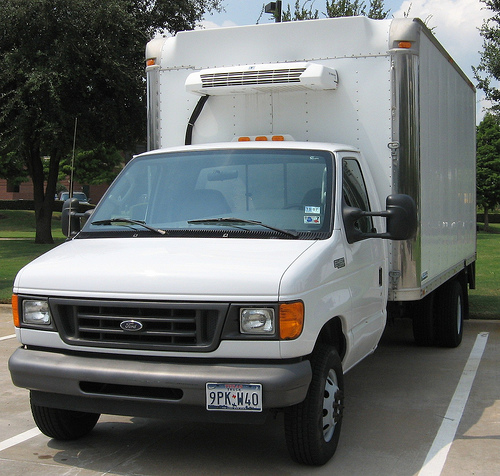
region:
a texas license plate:
[202, 370, 272, 431]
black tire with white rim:
[302, 368, 348, 462]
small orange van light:
[276, 288, 308, 350]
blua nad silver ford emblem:
[105, 308, 160, 356]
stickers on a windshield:
[294, 200, 322, 243]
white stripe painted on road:
[400, 329, 498, 474]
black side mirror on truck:
[331, 189, 415, 271]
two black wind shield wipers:
[80, 213, 270, 253]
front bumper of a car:
[10, 351, 295, 431]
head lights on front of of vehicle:
[0, 290, 292, 364]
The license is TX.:
[184, 376, 273, 430]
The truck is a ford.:
[109, 310, 154, 345]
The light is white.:
[241, 294, 303, 348]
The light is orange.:
[277, 294, 309, 341]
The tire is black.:
[293, 354, 383, 468]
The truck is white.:
[32, 19, 487, 471]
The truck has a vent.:
[178, 49, 351, 122]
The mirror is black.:
[358, 189, 438, 254]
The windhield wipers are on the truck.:
[79, 203, 314, 242]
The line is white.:
[397, 319, 457, 474]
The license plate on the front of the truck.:
[204, 376, 264, 415]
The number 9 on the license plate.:
[207, 389, 219, 404]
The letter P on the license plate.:
[214, 392, 225, 405]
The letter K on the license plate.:
[222, 387, 233, 408]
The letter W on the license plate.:
[236, 388, 243, 406]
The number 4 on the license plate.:
[244, 392, 254, 404]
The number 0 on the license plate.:
[251, 390, 258, 405]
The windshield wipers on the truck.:
[96, 206, 286, 243]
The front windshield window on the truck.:
[104, 150, 329, 237]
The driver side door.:
[336, 156, 393, 356]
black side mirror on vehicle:
[360, 166, 430, 257]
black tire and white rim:
[282, 350, 359, 471]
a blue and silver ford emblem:
[102, 315, 155, 345]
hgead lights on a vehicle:
[220, 285, 317, 367]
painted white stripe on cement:
[387, 325, 492, 473]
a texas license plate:
[184, 364, 279, 469]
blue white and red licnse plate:
[157, 379, 271, 454]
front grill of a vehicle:
[15, 285, 219, 385]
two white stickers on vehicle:
[248, 199, 333, 260]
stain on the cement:
[2, 445, 79, 471]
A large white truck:
[46, 14, 493, 451]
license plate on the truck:
[200, 377, 299, 426]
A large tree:
[3, 0, 207, 242]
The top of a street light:
[249, 0, 298, 20]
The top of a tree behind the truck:
[283, 0, 427, 26]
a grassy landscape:
[15, 205, 499, 305]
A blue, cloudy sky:
[157, 0, 487, 83]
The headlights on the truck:
[11, 288, 303, 350]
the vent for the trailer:
[186, 60, 362, 97]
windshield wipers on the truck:
[89, 204, 291, 239]